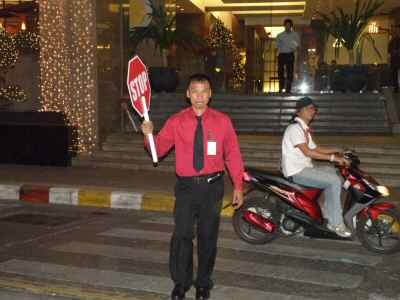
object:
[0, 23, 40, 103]
shubbery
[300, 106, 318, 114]
glasses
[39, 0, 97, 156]
post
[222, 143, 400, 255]
motorcycle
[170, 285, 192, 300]
shoes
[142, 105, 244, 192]
shirt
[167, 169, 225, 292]
pants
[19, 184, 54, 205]
block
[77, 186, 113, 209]
block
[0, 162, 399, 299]
ground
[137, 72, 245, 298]
man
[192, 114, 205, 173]
black tie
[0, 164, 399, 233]
sidewalk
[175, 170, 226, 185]
black belt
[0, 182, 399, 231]
curb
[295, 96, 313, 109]
hat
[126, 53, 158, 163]
sign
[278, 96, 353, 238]
man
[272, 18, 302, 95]
man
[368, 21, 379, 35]
light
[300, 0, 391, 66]
wall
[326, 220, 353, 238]
sneaker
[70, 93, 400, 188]
steps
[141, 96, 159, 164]
handle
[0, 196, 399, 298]
road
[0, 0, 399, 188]
building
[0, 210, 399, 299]
crosswalk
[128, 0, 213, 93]
plants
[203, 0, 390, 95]
lobby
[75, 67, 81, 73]
lights